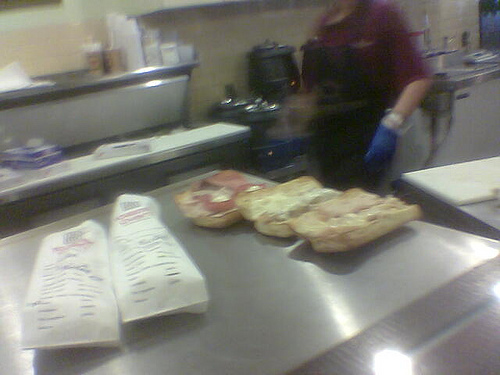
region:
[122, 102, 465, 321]
sandwiches on a counter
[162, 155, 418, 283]
three sandwiches on counter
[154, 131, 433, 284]
three sandwich on a counter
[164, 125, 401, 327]
three breads cut in half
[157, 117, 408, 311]
three sandwich breads toasted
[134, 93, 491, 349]
french bread that is toasted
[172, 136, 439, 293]
po boy bread toasted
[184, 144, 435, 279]
sandwiches on a counter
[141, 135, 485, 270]
sandwiches being made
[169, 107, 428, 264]
three sandwiches being made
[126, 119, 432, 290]
sandwiches on a table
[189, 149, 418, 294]
bread cut in half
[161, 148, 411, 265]
sandwich bread cut in half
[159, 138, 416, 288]
french bread cut in half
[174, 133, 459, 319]
po boy bread cut in half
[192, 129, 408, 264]
toasted french bread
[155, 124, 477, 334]
toasted po boy bread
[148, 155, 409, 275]
toasted sandwich bread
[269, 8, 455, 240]
a cook wearing a glove.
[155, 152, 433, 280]
food on a counter.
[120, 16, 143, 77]
a stack of containers.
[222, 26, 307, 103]
a pot on a stove.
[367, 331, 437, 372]
a light reflecting on a counter.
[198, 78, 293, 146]
a stove top.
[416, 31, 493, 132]
a sink in a kitchen.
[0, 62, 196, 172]
a counter top.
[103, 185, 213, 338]
a bag on a counter.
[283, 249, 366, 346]
a long light reflecting.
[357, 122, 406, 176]
blue glove on hand of person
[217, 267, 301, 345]
stainless steel table top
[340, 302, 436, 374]
light reflecting off stainless steel table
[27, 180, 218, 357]
two white bags laying on table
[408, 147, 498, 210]
white plastic cutting board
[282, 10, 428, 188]
person in black apron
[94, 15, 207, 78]
white cups stacked up table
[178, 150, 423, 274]
sandwiches sitting on table top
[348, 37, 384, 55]
white logo on front of shirt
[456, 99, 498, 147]
white paint on kitchen wall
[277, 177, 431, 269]
a food item on a table.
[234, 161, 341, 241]
a large food item.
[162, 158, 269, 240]
a food item on a counter.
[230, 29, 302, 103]
a large pot near a wall.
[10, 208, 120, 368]
a bag with writing on it.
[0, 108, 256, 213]
a food preparation area.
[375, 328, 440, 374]
light reflecting on a surface.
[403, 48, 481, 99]
a sink in a kitchen.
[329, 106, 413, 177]
a blue glove on a hand.